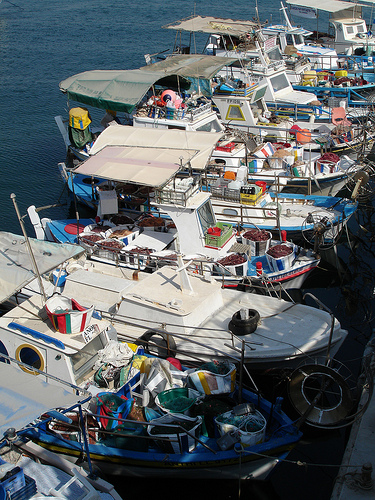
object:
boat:
[55, 107, 357, 250]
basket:
[155, 384, 201, 412]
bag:
[214, 405, 267, 443]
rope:
[245, 448, 368, 468]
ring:
[281, 357, 372, 427]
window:
[15, 344, 43, 374]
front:
[248, 189, 358, 247]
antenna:
[12, 194, 47, 299]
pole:
[84, 412, 182, 429]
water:
[2, 1, 374, 495]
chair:
[333, 106, 354, 134]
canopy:
[60, 65, 189, 113]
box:
[262, 246, 299, 268]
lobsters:
[273, 245, 286, 253]